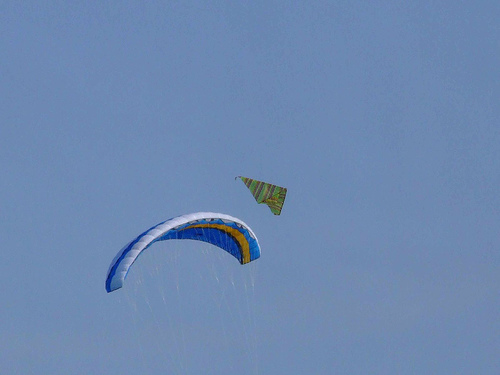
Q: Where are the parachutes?
A: In air.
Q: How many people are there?
A: None.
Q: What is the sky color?
A: Blue.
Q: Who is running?
A: No one.